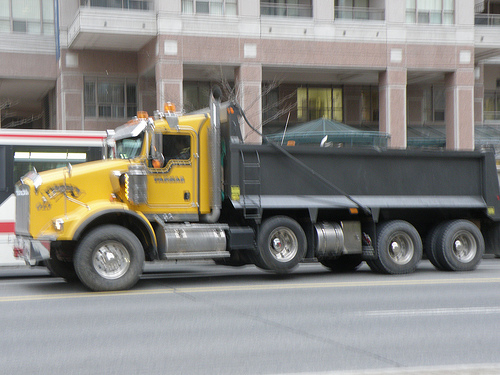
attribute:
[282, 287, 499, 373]
line — white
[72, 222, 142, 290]
wheel — black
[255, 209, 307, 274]
wheel — black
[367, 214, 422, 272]
wheel — black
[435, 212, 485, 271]
wheel — black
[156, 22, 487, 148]
pillars — brown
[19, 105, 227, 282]
truck cab — yellow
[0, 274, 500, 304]
line — yellow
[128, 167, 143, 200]
air filter — silver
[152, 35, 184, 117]
column — brown, white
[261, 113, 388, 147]
umbrella — green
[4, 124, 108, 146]
stripe — red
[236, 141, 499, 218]
bed — black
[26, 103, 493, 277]
truck — dump, yellow, black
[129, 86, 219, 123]
lights — orange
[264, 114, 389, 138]
tent — green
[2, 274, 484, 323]
line — yellow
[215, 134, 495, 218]
dump bed — black